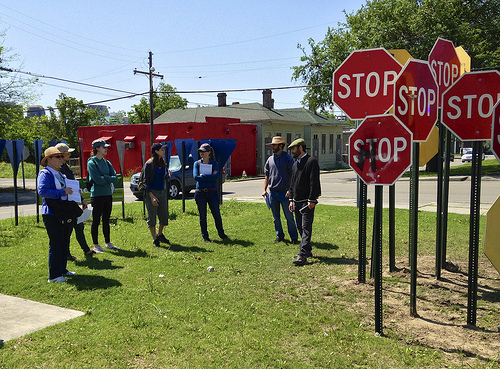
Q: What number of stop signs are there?
A: Five.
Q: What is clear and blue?
A: Sky.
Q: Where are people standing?
A: On grass.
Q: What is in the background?
A: Trees.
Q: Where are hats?
A: On people's heads.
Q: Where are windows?
A: On a house.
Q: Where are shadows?
A: On the grass.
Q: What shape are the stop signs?
A: Octagon.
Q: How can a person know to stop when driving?
A: Stop sign.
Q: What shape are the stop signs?
A: Octagons.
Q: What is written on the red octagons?
A: Stop.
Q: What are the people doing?
A: Standing.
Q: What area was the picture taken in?
A: Residential area.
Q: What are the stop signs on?
A: Poles.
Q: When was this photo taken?
A: During the daytime.